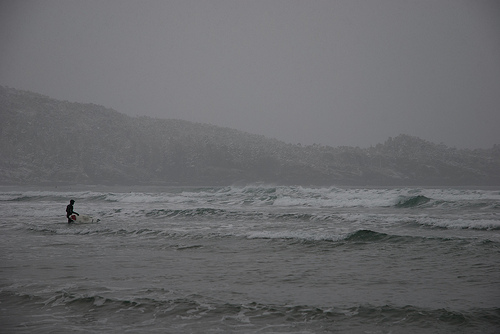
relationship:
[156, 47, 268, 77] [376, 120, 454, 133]
sky at dusk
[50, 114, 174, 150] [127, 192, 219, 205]
mountains past water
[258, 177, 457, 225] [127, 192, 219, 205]
waves in water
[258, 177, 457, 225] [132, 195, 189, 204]
waves with foam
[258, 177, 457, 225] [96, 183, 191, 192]
waves hitting shore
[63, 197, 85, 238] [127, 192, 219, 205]
person wading in water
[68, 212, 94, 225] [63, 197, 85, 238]
surfboard carried by a person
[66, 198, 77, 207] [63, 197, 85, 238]
head of a person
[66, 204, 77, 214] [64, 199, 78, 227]
torso of a person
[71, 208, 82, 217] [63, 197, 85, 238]
arm of a person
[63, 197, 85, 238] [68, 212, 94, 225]
person with a surfboard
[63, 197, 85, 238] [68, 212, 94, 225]
person holding white surfboard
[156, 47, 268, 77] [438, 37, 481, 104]
sky with clouds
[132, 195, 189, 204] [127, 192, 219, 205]
foam in water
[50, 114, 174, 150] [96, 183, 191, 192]
mountains next to shore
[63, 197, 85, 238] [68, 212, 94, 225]
person holding surfboard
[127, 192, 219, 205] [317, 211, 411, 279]
water that from sea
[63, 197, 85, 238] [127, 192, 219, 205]
person standing in water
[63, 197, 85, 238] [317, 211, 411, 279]
person standing in sea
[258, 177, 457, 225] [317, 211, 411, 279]
waves in sea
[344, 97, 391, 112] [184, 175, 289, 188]
foggy mountain on coast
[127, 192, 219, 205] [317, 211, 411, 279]
water in sea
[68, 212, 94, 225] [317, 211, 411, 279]
surfboard in sea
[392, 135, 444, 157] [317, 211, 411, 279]
trees growing by sea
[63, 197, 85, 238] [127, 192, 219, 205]
person in water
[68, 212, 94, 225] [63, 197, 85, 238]
surfboard in held by person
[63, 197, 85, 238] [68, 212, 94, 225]
person holding h surfboard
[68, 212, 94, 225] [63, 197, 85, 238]
surfboard held by person